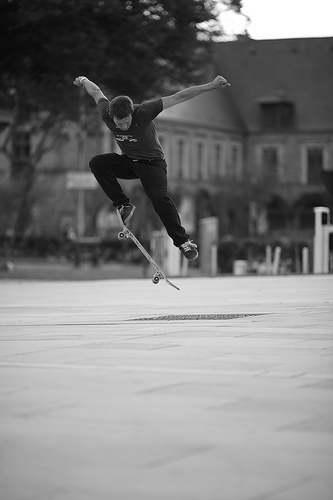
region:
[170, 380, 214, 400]
white cement on ground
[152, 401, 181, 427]
white cement on ground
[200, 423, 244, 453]
white cement on ground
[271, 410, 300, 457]
white cement on ground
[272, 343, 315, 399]
white cement on ground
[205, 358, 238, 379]
white cement on ground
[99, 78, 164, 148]
the head of a man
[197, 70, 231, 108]
the hand of a man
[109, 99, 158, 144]
the eyes of a man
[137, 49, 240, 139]
the arm of a man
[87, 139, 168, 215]
the leg of a man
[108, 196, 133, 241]
the foot of a man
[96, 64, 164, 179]
the body of a man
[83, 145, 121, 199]
the knees of a man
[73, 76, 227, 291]
a skater doing a trick on his skateboard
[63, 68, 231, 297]
a man doing a skateboard stunt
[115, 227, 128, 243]
the wheel of a skateboard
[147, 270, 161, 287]
the wheel of a skateboard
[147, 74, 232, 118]
the arm of a man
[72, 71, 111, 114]
the arm of a man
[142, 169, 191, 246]
the leg of a man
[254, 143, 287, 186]
the window of a building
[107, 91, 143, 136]
the head of a man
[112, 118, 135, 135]
the face of a man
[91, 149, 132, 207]
the leg of a man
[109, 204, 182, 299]
skateboard in the air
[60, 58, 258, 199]
skater has extended arms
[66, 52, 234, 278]
skater has black pants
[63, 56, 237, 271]
skater is in the air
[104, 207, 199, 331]
skateboard is above the gound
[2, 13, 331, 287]
skater is in front a home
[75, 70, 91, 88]
a clock on wrist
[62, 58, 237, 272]
skater wears black cloths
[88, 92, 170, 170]
a black tee shirt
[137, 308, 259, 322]
a shadow on the pavement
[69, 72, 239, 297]
boy wearing black pants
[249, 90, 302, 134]
chimney on a house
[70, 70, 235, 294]
boy with arms extended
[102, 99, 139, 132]
the head of a man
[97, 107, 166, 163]
the shirt of a man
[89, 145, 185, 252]
the pants of a man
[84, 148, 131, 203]
the right leg of a man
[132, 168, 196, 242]
the left leg of a man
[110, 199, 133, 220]
the right shoe of a man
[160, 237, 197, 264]
the left shoe of a man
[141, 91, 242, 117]
the left arm of a man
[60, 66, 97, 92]
the right hand of a man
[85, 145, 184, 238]
boy wearing black pants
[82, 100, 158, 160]
boy wearing a gray shirt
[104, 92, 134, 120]
boy with brown hair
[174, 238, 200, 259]
boy wearing gray shoes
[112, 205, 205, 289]
boy on a skateboard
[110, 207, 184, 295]
skate board in the air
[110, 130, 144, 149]
white logo on the shirt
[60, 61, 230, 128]
boy with his arm out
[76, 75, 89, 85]
boy wearing a white band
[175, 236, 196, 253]
white laces in the shoe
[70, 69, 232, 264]
man making jump on skateboard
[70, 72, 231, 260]
man dressed in blue jeans and t shirt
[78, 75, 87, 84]
watch on mans wrist